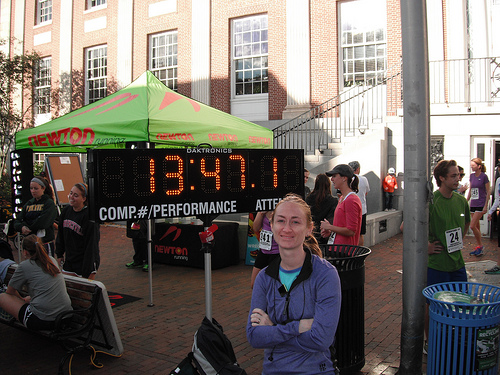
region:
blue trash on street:
[417, 279, 497, 371]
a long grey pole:
[396, 0, 432, 373]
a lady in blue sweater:
[242, 189, 347, 373]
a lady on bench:
[0, 228, 102, 373]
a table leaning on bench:
[1, 265, 126, 373]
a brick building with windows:
[3, 1, 498, 253]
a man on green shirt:
[421, 155, 476, 355]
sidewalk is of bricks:
[1, 206, 498, 373]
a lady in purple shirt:
[246, 208, 278, 296]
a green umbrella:
[10, 66, 276, 312]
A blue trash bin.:
[421, 279, 498, 371]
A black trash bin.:
[319, 246, 371, 372]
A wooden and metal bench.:
[4, 264, 105, 373]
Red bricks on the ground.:
[0, 204, 498, 373]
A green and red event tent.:
[9, 72, 270, 324]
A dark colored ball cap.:
[324, 164, 353, 178]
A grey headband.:
[30, 176, 49, 190]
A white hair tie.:
[33, 238, 44, 246]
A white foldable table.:
[61, 272, 124, 361]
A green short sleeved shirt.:
[422, 194, 468, 271]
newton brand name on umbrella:
[20, 127, 127, 145]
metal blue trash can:
[427, 272, 497, 358]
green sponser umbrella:
[26, 70, 273, 152]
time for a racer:
[146, 153, 290, 197]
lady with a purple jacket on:
[240, 185, 354, 371]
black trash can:
[330, 237, 370, 371]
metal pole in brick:
[398, 3, 418, 373]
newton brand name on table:
[155, 237, 194, 264]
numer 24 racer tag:
[445, 223, 464, 258]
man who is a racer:
[438, 151, 469, 281]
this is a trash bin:
[426, 280, 498, 341]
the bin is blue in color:
[434, 335, 460, 354]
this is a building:
[33, 8, 488, 60]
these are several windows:
[148, 0, 393, 76]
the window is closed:
[230, 25, 270, 95]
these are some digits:
[138, 153, 288, 198]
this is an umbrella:
[62, 101, 194, 143]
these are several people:
[276, 162, 476, 365]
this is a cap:
[326, 163, 353, 173]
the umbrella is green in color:
[121, 108, 134, 122]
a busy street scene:
[23, 18, 490, 343]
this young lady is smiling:
[94, 133, 469, 333]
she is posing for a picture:
[200, 185, 357, 373]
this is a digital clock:
[75, 127, 320, 230]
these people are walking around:
[331, 144, 498, 276]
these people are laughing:
[5, 168, 95, 317]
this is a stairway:
[249, 43, 494, 169]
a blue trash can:
[403, 266, 497, 374]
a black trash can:
[312, 242, 374, 368]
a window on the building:
[215, 10, 290, 102]